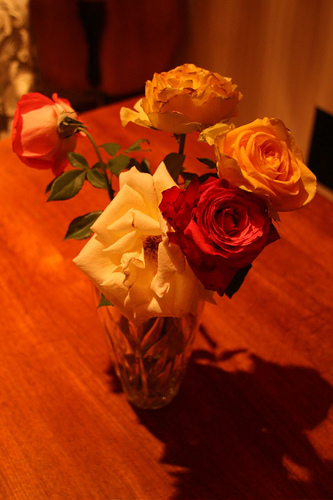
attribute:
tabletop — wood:
[0, 104, 331, 498]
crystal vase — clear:
[96, 296, 198, 407]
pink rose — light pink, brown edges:
[119, 63, 244, 137]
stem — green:
[59, 118, 115, 196]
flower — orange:
[196, 115, 317, 211]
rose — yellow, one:
[121, 59, 243, 135]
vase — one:
[90, 279, 204, 409]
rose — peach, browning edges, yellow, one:
[197, 116, 318, 210]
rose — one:
[147, 47, 254, 131]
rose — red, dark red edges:
[111, 181, 326, 313]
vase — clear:
[98, 284, 233, 402]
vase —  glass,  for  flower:
[84, 282, 210, 417]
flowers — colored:
[88, 128, 255, 319]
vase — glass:
[96, 297, 222, 411]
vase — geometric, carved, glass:
[101, 312, 187, 403]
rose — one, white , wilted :
[119, 62, 244, 131]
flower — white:
[119, 44, 279, 254]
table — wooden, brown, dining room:
[2, 91, 332, 499]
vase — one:
[112, 309, 217, 409]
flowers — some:
[55, 78, 263, 281]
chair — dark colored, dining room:
[274, 90, 331, 191]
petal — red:
[189, 226, 206, 247]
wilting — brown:
[149, 69, 228, 100]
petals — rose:
[119, 68, 250, 134]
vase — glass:
[107, 307, 185, 381]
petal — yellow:
[154, 86, 191, 109]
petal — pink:
[8, 89, 62, 159]